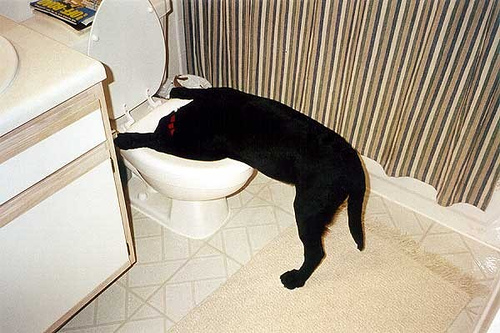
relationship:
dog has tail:
[106, 79, 371, 294] [345, 170, 375, 254]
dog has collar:
[106, 79, 371, 294] [161, 109, 181, 141]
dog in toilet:
[106, 79, 371, 294] [90, 3, 247, 244]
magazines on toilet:
[30, 0, 98, 29] [90, 3, 247, 244]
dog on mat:
[106, 79, 371, 294] [204, 227, 488, 331]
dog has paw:
[106, 79, 371, 294] [113, 129, 149, 151]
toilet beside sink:
[90, 3, 247, 244] [1, 16, 58, 120]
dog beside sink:
[106, 79, 371, 294] [1, 16, 58, 120]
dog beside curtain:
[106, 79, 371, 294] [194, 4, 499, 81]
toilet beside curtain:
[90, 3, 247, 244] [194, 4, 499, 81]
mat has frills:
[204, 227, 488, 331] [401, 236, 488, 300]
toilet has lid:
[90, 3, 247, 244] [103, 0, 172, 116]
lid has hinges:
[103, 0, 172, 116] [116, 84, 165, 124]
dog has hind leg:
[106, 79, 371, 294] [279, 198, 335, 292]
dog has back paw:
[106, 79, 371, 294] [278, 262, 308, 299]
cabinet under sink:
[1, 150, 142, 310] [1, 16, 58, 120]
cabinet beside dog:
[1, 150, 142, 310] [106, 79, 371, 294]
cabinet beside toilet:
[1, 150, 142, 310] [90, 3, 247, 244]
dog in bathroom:
[106, 79, 371, 294] [24, 4, 491, 327]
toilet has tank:
[90, 3, 247, 244] [47, 1, 174, 90]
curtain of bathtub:
[166, 8, 494, 212] [331, 135, 494, 252]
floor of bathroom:
[78, 186, 498, 323] [6, 55, 442, 333]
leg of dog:
[277, 184, 339, 292] [118, 64, 379, 285]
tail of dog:
[342, 166, 372, 256] [119, 60, 426, 295]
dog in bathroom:
[106, 79, 371, 294] [0, 60, 500, 329]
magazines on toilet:
[30, 0, 98, 26] [87, 55, 312, 240]